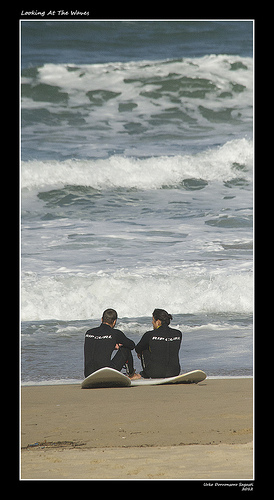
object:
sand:
[20, 382, 254, 480]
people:
[135, 307, 182, 378]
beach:
[19, 383, 261, 484]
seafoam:
[24, 58, 253, 115]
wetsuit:
[136, 326, 183, 378]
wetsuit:
[84, 326, 135, 378]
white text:
[151, 337, 180, 342]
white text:
[86, 334, 112, 340]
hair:
[103, 308, 117, 322]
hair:
[152, 309, 172, 325]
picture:
[22, 17, 254, 480]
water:
[23, 32, 257, 336]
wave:
[22, 152, 254, 184]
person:
[84, 306, 141, 383]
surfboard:
[81, 367, 132, 388]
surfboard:
[131, 369, 207, 385]